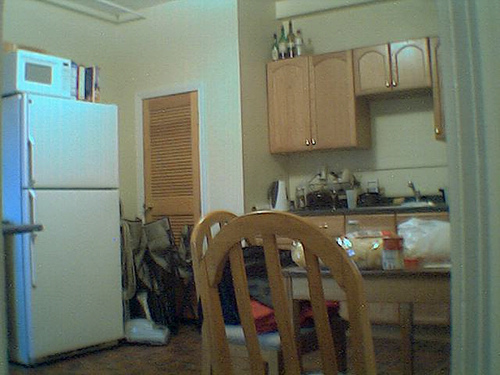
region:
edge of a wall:
[212, 107, 254, 164]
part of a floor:
[156, 339, 175, 361]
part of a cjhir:
[243, 249, 275, 298]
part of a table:
[377, 253, 407, 280]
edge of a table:
[363, 245, 423, 300]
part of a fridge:
[44, 237, 99, 304]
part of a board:
[280, 92, 345, 222]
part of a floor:
[141, 333, 172, 373]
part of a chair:
[199, 292, 235, 340]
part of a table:
[378, 246, 430, 338]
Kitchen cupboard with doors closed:
[263, 50, 367, 160]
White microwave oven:
[8, 42, 77, 101]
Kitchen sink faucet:
[394, 176, 436, 209]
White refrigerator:
[1, 91, 135, 363]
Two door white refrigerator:
[1, 88, 132, 362]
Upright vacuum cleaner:
[108, 195, 171, 355]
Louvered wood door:
[136, 85, 205, 275]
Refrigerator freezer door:
[11, 90, 126, 194]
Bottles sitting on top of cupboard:
[267, 18, 308, 62]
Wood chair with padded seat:
[186, 206, 349, 370]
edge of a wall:
[232, 142, 253, 176]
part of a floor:
[132, 315, 169, 368]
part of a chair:
[247, 287, 303, 355]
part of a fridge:
[66, 223, 103, 275]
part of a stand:
[396, 322, 411, 353]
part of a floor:
[159, 330, 186, 365]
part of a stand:
[389, 303, 414, 350]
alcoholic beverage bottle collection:
[261, 11, 318, 69]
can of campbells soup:
[364, 227, 411, 282]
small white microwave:
[10, 32, 99, 137]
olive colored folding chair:
[122, 172, 244, 334]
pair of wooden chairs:
[172, 204, 387, 368]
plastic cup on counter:
[340, 182, 365, 212]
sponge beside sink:
[387, 190, 407, 212]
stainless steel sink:
[383, 168, 443, 220]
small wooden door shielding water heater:
[130, 68, 206, 323]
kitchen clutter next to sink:
[266, 159, 367, 213]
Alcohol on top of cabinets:
[265, 17, 319, 60]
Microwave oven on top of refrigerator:
[3, 50, 77, 94]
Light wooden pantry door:
[140, 90, 199, 285]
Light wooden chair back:
[188, 209, 375, 374]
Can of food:
[380, 233, 407, 271]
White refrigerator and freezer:
[0, 95, 125, 366]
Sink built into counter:
[382, 177, 434, 212]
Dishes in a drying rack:
[293, 165, 369, 212]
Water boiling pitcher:
[266, 177, 293, 212]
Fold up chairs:
[121, 215, 197, 338]